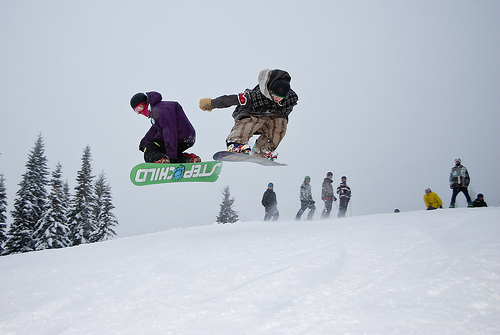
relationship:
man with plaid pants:
[198, 67, 301, 161] [225, 112, 287, 152]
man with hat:
[198, 67, 301, 161] [266, 69, 290, 98]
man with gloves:
[129, 90, 203, 166] [203, 97, 215, 110]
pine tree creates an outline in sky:
[66, 142, 99, 245] [69, 142, 99, 181]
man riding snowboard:
[129, 90, 203, 166] [129, 160, 221, 183]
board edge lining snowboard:
[173, 177, 198, 184] [129, 160, 221, 183]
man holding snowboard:
[129, 90, 203, 166] [129, 160, 221, 183]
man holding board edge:
[129, 90, 203, 166] [173, 177, 198, 184]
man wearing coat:
[423, 187, 443, 210] [424, 192, 441, 207]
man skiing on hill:
[423, 187, 443, 210] [92, 210, 484, 326]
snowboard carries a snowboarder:
[129, 160, 223, 187] [128, 90, 204, 158]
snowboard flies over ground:
[121, 159, 226, 181] [335, 152, 414, 209]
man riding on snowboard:
[133, 93, 198, 163] [121, 159, 226, 181]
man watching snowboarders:
[292, 175, 317, 219] [103, 52, 315, 180]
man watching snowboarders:
[261, 182, 280, 221] [103, 52, 315, 180]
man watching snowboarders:
[318, 168, 336, 217] [103, 52, 315, 180]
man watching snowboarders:
[335, 172, 350, 219] [103, 52, 315, 180]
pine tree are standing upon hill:
[66, 142, 99, 245] [3, 207, 293, 322]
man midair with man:
[129, 90, 203, 166] [203, 52, 302, 170]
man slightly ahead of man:
[203, 52, 302, 170] [129, 90, 203, 166]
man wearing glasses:
[129, 90, 203, 166] [111, 87, 171, 118]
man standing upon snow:
[449, 157, 476, 209] [291, 203, 483, 274]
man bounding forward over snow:
[409, 119, 486, 216] [213, 217, 461, 327]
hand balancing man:
[197, 96, 220, 111] [409, 119, 486, 216]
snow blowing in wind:
[10, 242, 498, 334] [13, 11, 481, 222]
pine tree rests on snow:
[2, 130, 56, 255] [0, 128, 500, 335]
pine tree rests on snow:
[32, 162, 74, 251] [0, 128, 500, 335]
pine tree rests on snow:
[91, 171, 119, 243] [0, 128, 500, 335]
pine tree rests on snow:
[66, 142, 99, 245] [0, 128, 500, 335]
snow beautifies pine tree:
[0, 128, 500, 335] [2, 130, 56, 255]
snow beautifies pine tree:
[0, 128, 500, 335] [32, 162, 74, 251]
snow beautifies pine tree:
[0, 128, 500, 335] [91, 171, 119, 243]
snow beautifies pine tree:
[0, 128, 500, 335] [66, 142, 99, 245]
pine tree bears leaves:
[32, 162, 74, 251] [34, 162, 74, 251]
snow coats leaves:
[0, 128, 500, 335] [34, 162, 74, 251]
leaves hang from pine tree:
[34, 162, 74, 251] [32, 162, 74, 251]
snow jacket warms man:
[422, 192, 443, 207] [418, 189, 447, 213]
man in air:
[129, 90, 203, 166] [304, 64, 415, 151]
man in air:
[198, 67, 301, 161] [317, 62, 421, 178]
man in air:
[129, 90, 203, 166] [282, 102, 401, 183]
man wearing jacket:
[198, 67, 301, 161] [149, 99, 192, 154]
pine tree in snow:
[32, 162, 74, 251] [10, 210, 481, 327]